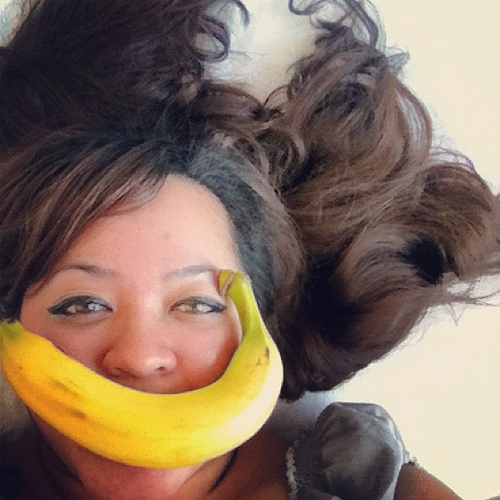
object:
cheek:
[173, 321, 241, 385]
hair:
[0, 0, 500, 402]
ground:
[437, 144, 459, 174]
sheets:
[377, 1, 499, 193]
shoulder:
[317, 401, 461, 499]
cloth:
[278, 404, 412, 498]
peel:
[0, 268, 283, 470]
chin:
[118, 464, 195, 481]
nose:
[102, 310, 176, 380]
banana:
[0, 268, 283, 470]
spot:
[28, 368, 93, 431]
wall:
[270, 275, 498, 499]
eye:
[49, 295, 114, 318]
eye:
[167, 297, 226, 315]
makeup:
[45, 295, 114, 317]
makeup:
[171, 292, 228, 316]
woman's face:
[18, 173, 247, 471]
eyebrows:
[166, 264, 220, 278]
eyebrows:
[49, 261, 116, 276]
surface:
[0, 0, 498, 497]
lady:
[0, 3, 496, 499]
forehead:
[65, 170, 230, 277]